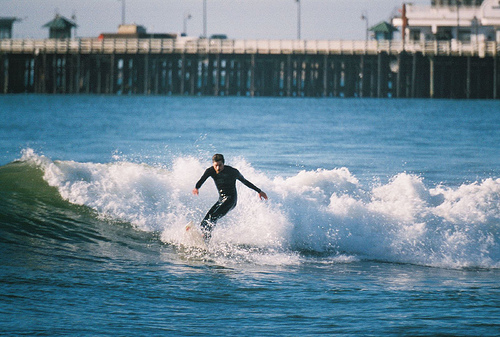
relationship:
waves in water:
[158, 281, 269, 324] [163, 294, 285, 324]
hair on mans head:
[203, 122, 242, 190] [202, 156, 239, 173]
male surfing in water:
[191, 153, 270, 246] [10, 174, 494, 332]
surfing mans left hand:
[0, 149, 499, 283] [244, 173, 260, 210]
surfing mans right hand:
[0, 149, 499, 283] [179, 166, 209, 250]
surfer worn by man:
[193, 153, 269, 245] [168, 130, 283, 309]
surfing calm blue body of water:
[0, 149, 499, 283] [14, 121, 497, 295]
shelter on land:
[37, 51, 81, 73] [0, 100, 60, 103]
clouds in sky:
[160, 0, 324, 37] [285, 99, 299, 106]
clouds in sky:
[160, 0, 324, 37] [36, 51, 70, 63]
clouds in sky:
[160, 0, 324, 37] [272, 99, 370, 115]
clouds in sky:
[160, 0, 324, 37] [63, 51, 101, 73]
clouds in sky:
[160, 0, 324, 37] [354, 99, 465, 143]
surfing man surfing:
[0, 149, 499, 283] [158, 128, 275, 262]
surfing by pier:
[29, 76, 497, 337] [52, 101, 470, 327]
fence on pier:
[47, 105, 497, 133] [2, 87, 495, 113]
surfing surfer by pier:
[0, 149, 499, 283] [34, 262, 494, 337]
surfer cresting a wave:
[156, 140, 276, 337] [14, 186, 498, 311]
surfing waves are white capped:
[0, 149, 499, 283] [3, 186, 483, 319]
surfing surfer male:
[0, 149, 499, 283] [152, 145, 271, 336]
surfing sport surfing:
[0, 149, 499, 283] [148, 117, 297, 320]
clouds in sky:
[160, 0, 324, 37] [352, 111, 459, 162]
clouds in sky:
[160, 0, 324, 37] [34, 72, 91, 105]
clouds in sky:
[160, 0, 324, 37] [73, 101, 145, 141]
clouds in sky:
[160, 0, 324, 37] [1, 0, 439, 37]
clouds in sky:
[2, 0, 404, 38] [0, 0, 402, 40]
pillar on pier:
[0, 50, 499, 100] [0, 32, 500, 53]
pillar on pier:
[371, 49, 388, 104] [0, 35, 499, 60]